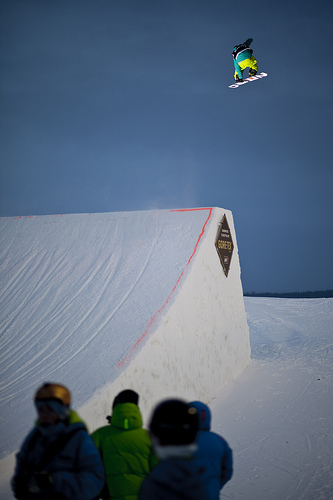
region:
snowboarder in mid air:
[226, 37, 267, 88]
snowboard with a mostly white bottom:
[226, 72, 265, 89]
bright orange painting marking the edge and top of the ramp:
[117, 208, 213, 372]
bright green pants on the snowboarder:
[233, 58, 254, 73]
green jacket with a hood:
[90, 404, 147, 494]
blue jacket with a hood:
[189, 401, 231, 497]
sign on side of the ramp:
[215, 213, 233, 277]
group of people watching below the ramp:
[11, 381, 230, 497]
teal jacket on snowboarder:
[233, 44, 254, 77]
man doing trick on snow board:
[201, 36, 278, 94]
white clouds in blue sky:
[27, 26, 59, 60]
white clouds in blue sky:
[244, 190, 289, 227]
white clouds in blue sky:
[177, 162, 211, 196]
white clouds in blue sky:
[88, 86, 124, 121]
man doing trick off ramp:
[223, 30, 278, 103]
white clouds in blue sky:
[282, 158, 318, 206]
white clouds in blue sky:
[196, 116, 220, 150]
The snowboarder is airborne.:
[226, 36, 266, 88]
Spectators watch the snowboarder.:
[10, 382, 232, 499]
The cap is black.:
[113, 387, 140, 403]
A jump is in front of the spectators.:
[1, 205, 251, 377]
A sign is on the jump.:
[214, 214, 232, 276]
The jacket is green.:
[238, 52, 249, 60]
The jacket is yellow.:
[241, 60, 256, 68]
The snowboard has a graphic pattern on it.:
[228, 72, 267, 89]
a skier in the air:
[213, 28, 276, 103]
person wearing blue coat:
[8, 373, 107, 498]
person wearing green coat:
[87, 385, 160, 499]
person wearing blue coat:
[187, 395, 238, 498]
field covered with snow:
[232, 291, 331, 497]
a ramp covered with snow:
[1, 209, 236, 391]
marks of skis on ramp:
[8, 233, 144, 357]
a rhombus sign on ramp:
[212, 209, 239, 281]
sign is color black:
[212, 212, 237, 279]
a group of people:
[2, 362, 231, 493]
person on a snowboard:
[220, 32, 278, 97]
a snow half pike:
[10, 196, 239, 392]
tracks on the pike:
[9, 220, 142, 355]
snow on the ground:
[253, 300, 325, 494]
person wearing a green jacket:
[90, 395, 149, 489]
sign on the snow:
[206, 209, 243, 275]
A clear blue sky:
[0, 0, 333, 292]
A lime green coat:
[83, 398, 148, 489]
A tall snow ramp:
[0, 201, 245, 493]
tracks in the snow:
[227, 333, 324, 494]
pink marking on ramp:
[109, 201, 206, 361]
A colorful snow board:
[221, 67, 263, 84]